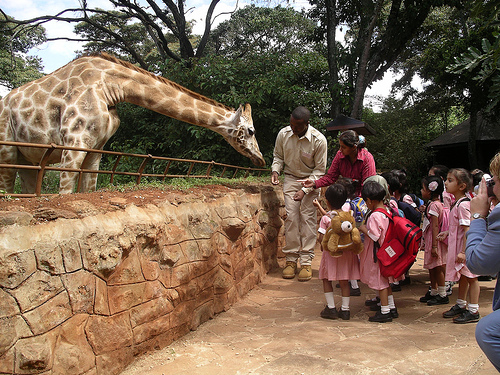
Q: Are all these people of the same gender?
A: No, they are both male and female.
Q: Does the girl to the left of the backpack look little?
A: Yes, the girl is little.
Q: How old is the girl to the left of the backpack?
A: The girl is little.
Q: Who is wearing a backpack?
A: The girl is wearing a backpack.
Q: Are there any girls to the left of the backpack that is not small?
A: Yes, there is a girl to the left of the backpack.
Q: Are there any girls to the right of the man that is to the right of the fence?
A: Yes, there is a girl to the right of the man.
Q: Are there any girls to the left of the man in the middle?
A: No, the girl is to the right of the man.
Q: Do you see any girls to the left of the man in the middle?
A: No, the girl is to the right of the man.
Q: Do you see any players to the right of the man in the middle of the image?
A: No, there is a girl to the right of the man.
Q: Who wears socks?
A: The girl wears socks.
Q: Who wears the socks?
A: The girl wears socks.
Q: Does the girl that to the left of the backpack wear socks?
A: Yes, the girl wears socks.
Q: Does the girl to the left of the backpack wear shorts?
A: No, the girl wears socks.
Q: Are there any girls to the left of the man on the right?
A: Yes, there is a girl to the left of the man.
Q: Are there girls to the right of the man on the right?
A: No, the girl is to the left of the man.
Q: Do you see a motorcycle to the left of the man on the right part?
A: No, there is a girl to the left of the man.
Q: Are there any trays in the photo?
A: No, there are no trays.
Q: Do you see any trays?
A: No, there are no trays.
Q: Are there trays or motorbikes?
A: No, there are no trays or motorbikes.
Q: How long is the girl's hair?
A: The hair is short.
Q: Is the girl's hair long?
A: No, the hair is short.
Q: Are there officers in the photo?
A: No, there are no officers.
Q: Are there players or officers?
A: No, there are no officers or players.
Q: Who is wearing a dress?
A: The girl is wearing a dress.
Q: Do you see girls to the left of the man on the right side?
A: Yes, there is a girl to the left of the man.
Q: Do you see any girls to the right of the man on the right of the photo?
A: No, the girl is to the left of the man.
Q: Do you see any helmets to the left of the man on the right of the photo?
A: No, there is a girl to the left of the man.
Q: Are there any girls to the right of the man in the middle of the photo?
A: Yes, there is a girl to the right of the man.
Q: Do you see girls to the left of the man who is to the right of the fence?
A: No, the girl is to the right of the man.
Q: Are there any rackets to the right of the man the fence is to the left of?
A: No, there is a girl to the right of the man.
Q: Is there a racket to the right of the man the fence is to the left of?
A: No, there is a girl to the right of the man.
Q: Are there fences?
A: Yes, there is a fence.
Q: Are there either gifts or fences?
A: Yes, there is a fence.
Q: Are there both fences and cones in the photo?
A: No, there is a fence but no cones.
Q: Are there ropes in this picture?
A: No, there are no ropes.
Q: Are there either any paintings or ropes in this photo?
A: No, there are no ropes or paintings.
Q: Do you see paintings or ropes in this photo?
A: No, there are no ropes or paintings.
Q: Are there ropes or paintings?
A: No, there are no ropes or paintings.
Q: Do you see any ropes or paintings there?
A: No, there are no ropes or paintings.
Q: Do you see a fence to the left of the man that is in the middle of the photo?
A: Yes, there is a fence to the left of the man.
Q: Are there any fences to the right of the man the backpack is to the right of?
A: No, the fence is to the left of the man.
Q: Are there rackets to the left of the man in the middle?
A: No, there is a fence to the left of the man.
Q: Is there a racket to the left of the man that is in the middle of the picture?
A: No, there is a fence to the left of the man.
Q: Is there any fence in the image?
A: Yes, there is a fence.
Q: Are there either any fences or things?
A: Yes, there is a fence.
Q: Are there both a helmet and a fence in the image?
A: No, there is a fence but no helmets.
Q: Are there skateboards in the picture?
A: No, there are no skateboards.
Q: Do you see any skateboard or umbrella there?
A: No, there are no skateboards or umbrellas.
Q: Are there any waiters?
A: No, there are no waiters.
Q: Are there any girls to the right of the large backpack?
A: Yes, there is a girl to the right of the backpack.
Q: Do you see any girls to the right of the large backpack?
A: Yes, there is a girl to the right of the backpack.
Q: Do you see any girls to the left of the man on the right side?
A: Yes, there is a girl to the left of the man.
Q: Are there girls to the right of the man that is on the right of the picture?
A: No, the girl is to the left of the man.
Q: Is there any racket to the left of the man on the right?
A: No, there is a girl to the left of the man.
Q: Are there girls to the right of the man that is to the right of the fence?
A: Yes, there is a girl to the right of the man.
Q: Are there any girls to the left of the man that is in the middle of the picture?
A: No, the girl is to the right of the man.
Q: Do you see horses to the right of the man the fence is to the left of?
A: No, there is a girl to the right of the man.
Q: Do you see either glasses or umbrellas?
A: No, there are no glasses or umbrellas.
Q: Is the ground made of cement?
A: Yes, the ground is made of cement.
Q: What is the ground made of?
A: The ground is made of concrete.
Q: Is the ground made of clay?
A: No, the ground is made of cement.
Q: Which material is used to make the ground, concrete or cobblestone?
A: The ground is made of concrete.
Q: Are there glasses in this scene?
A: No, there are no glasses.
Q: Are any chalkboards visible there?
A: No, there are no chalkboards.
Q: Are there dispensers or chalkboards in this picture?
A: No, there are no chalkboards or dispensers.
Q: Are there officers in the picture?
A: No, there are no officers.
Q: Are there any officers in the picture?
A: No, there are no officers.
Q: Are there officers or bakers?
A: No, there are no officers or bakers.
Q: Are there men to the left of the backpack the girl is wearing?
A: Yes, there is a man to the left of the backpack.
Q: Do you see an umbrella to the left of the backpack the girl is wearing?
A: No, there is a man to the left of the backpack.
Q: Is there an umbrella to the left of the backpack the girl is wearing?
A: No, there is a man to the left of the backpack.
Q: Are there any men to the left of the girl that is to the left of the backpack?
A: Yes, there is a man to the left of the girl.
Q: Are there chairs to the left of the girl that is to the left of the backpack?
A: No, there is a man to the left of the girl.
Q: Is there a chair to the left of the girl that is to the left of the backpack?
A: No, there is a man to the left of the girl.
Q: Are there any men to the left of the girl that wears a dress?
A: Yes, there is a man to the left of the girl.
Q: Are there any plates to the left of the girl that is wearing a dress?
A: No, there is a man to the left of the girl.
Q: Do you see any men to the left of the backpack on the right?
A: Yes, there is a man to the left of the backpack.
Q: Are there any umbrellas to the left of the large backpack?
A: No, there is a man to the left of the backpack.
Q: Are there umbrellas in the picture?
A: No, there are no umbrellas.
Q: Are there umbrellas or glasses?
A: No, there are no umbrellas or glasses.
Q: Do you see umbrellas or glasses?
A: No, there are no umbrellas or glasses.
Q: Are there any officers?
A: No, there are no officers.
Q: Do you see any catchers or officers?
A: No, there are no officers or catchers.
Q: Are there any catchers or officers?
A: No, there are no officers or catchers.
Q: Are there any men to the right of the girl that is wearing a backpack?
A: Yes, there is a man to the right of the girl.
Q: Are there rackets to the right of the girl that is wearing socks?
A: No, there is a man to the right of the girl.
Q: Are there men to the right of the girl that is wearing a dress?
A: Yes, there is a man to the right of the girl.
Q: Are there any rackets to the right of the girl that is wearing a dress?
A: No, there is a man to the right of the girl.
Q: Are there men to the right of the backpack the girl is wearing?
A: Yes, there is a man to the right of the backpack.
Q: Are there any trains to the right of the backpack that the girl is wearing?
A: No, there is a man to the right of the backpack.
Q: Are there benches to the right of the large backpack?
A: No, there is a man to the right of the backpack.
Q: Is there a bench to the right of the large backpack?
A: No, there is a man to the right of the backpack.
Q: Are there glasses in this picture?
A: No, there are no glasses.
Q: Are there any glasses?
A: No, there are no glasses.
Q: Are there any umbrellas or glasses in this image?
A: No, there are no glasses or umbrellas.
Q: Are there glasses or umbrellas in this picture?
A: No, there are no glasses or umbrellas.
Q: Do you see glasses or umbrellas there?
A: No, there are no glasses or umbrellas.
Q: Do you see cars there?
A: No, there are no cars.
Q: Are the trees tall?
A: Yes, the trees are tall.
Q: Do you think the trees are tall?
A: Yes, the trees are tall.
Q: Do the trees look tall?
A: Yes, the trees are tall.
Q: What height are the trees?
A: The trees are tall.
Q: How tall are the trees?
A: The trees are tall.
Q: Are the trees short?
A: No, the trees are tall.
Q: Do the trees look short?
A: No, the trees are tall.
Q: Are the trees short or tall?
A: The trees are tall.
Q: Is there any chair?
A: No, there are no chairs.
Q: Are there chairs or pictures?
A: No, there are no chairs or pictures.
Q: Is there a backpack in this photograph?
A: Yes, there is a backpack.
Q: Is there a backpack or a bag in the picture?
A: Yes, there is a backpack.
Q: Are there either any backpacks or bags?
A: Yes, there is a backpack.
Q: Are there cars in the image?
A: No, there are no cars.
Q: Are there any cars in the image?
A: No, there are no cars.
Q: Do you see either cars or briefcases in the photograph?
A: No, there are no cars or briefcases.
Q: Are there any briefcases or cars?
A: No, there are no cars or briefcases.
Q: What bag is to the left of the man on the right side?
A: The bag is a backpack.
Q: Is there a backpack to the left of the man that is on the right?
A: Yes, there is a backpack to the left of the man.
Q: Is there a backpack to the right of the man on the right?
A: No, the backpack is to the left of the man.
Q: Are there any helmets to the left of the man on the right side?
A: No, there is a backpack to the left of the man.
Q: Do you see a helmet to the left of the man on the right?
A: No, there is a backpack to the left of the man.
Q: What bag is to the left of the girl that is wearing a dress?
A: The bag is a backpack.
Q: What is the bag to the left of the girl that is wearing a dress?
A: The bag is a backpack.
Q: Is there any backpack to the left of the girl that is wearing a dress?
A: Yes, there is a backpack to the left of the girl.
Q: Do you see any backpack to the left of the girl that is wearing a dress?
A: Yes, there is a backpack to the left of the girl.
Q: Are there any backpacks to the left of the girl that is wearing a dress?
A: Yes, there is a backpack to the left of the girl.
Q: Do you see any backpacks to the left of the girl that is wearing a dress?
A: Yes, there is a backpack to the left of the girl.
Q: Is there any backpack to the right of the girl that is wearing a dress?
A: No, the backpack is to the left of the girl.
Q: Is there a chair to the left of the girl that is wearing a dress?
A: No, there is a backpack to the left of the girl.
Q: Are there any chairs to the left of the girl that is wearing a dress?
A: No, there is a backpack to the left of the girl.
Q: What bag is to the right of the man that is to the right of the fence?
A: The bag is a backpack.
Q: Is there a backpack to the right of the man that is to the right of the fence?
A: Yes, there is a backpack to the right of the man.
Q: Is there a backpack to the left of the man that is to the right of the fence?
A: No, the backpack is to the right of the man.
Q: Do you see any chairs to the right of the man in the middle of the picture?
A: No, there is a backpack to the right of the man.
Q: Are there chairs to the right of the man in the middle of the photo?
A: No, there is a backpack to the right of the man.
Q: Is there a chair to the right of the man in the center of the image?
A: No, there is a backpack to the right of the man.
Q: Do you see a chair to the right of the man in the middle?
A: No, there is a backpack to the right of the man.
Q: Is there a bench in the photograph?
A: No, there are no benches.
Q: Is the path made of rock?
A: Yes, the path is made of rock.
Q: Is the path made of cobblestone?
A: No, the path is made of rock.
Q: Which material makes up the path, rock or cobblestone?
A: The path is made of rock.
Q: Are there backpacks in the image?
A: Yes, there is a backpack.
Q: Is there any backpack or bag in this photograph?
A: Yes, there is a backpack.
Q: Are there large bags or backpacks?
A: Yes, there is a large backpack.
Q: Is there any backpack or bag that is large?
A: Yes, the backpack is large.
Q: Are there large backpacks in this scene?
A: Yes, there is a large backpack.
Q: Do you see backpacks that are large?
A: Yes, there is a backpack that is large.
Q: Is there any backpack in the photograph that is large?
A: Yes, there is a backpack that is large.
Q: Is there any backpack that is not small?
A: Yes, there is a large backpack.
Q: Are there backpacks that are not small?
A: Yes, there is a large backpack.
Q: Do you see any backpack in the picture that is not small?
A: Yes, there is a large backpack.